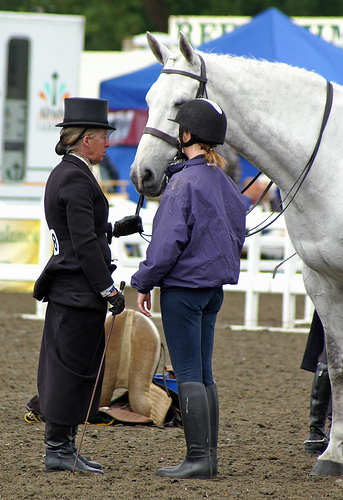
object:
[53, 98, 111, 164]
head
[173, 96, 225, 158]
head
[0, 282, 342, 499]
dirt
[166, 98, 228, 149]
helmet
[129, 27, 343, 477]
horse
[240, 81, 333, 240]
harness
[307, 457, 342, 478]
shoe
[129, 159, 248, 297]
jacket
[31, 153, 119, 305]
black jacket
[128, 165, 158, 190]
horse nose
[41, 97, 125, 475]
woman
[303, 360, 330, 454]
shoes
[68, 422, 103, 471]
boot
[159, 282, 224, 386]
blue jeans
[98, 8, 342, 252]
tent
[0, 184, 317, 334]
fence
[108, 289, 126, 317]
glove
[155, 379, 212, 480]
boot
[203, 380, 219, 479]
boot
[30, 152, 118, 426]
garment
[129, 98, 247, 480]
women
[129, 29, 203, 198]
head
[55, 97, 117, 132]
hat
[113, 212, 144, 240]
gloves